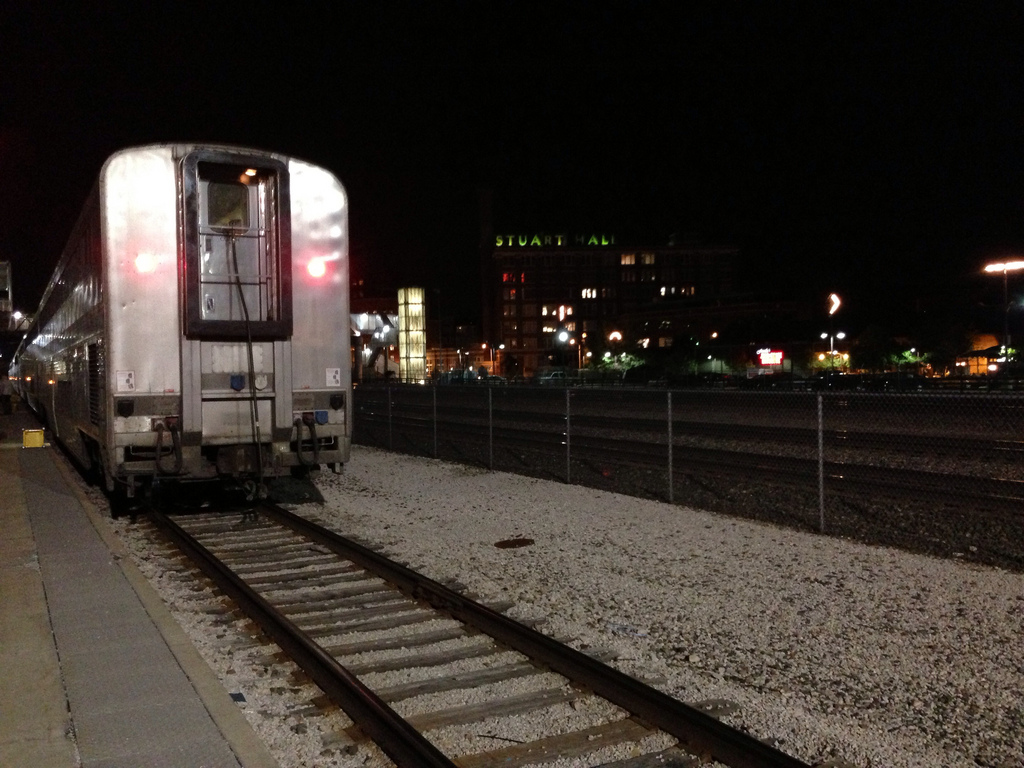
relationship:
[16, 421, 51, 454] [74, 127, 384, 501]
stool for trains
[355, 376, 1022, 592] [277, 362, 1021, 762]
fence separate tracks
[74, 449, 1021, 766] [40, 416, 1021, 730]
gravel next tracks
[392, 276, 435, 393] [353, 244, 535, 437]
light in train station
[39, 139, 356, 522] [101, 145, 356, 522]
train back has train back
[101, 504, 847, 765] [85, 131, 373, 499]
train tracks under train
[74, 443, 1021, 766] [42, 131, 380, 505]
rocks next train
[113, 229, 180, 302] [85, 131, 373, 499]
red light on train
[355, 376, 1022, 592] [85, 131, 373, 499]
fence next train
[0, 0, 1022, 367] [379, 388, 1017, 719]
sky above land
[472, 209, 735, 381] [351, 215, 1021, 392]
building on commercial district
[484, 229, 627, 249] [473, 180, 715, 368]
letter on building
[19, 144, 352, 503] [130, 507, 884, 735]
silver train on track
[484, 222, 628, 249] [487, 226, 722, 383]
letter on building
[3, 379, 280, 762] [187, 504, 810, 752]
walkway beside train track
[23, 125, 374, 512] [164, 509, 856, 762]
train on track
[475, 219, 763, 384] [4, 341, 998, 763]
hotel adjacent to station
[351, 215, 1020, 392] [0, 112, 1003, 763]
commercial district near station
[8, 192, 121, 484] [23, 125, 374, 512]
side of train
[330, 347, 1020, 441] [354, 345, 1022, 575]
top of fence